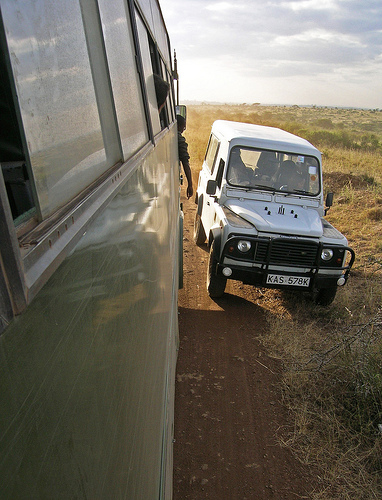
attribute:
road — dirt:
[180, 228, 309, 496]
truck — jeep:
[193, 116, 356, 305]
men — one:
[176, 103, 200, 219]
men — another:
[139, 61, 173, 134]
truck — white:
[185, 102, 364, 286]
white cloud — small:
[270, 0, 340, 14]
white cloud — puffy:
[275, 27, 361, 46]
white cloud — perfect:
[203, 0, 256, 18]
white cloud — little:
[355, 55, 380, 75]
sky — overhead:
[177, 0, 380, 102]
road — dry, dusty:
[198, 320, 251, 455]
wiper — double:
[292, 186, 316, 195]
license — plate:
[266, 272, 311, 288]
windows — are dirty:
[9, 0, 174, 322]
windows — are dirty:
[223, 136, 328, 203]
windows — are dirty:
[197, 125, 223, 174]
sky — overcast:
[265, 42, 344, 82]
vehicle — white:
[189, 120, 359, 305]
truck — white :
[196, 94, 361, 325]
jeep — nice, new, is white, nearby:
[193, 119, 355, 306]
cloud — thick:
[250, 32, 380, 69]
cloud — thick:
[228, 56, 341, 84]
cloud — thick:
[159, 0, 380, 63]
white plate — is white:
[265, 271, 311, 290]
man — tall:
[172, 93, 193, 193]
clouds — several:
[223, 33, 341, 81]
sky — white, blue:
[157, 0, 380, 109]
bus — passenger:
[3, 4, 197, 496]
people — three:
[220, 142, 314, 192]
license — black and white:
[264, 272, 309, 287]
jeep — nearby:
[163, 110, 361, 305]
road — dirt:
[178, 288, 292, 499]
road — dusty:
[204, 320, 228, 422]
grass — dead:
[266, 320, 380, 498]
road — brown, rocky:
[181, 296, 276, 494]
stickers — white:
[308, 165, 317, 185]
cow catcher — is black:
[231, 231, 353, 285]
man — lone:
[285, 177, 327, 194]